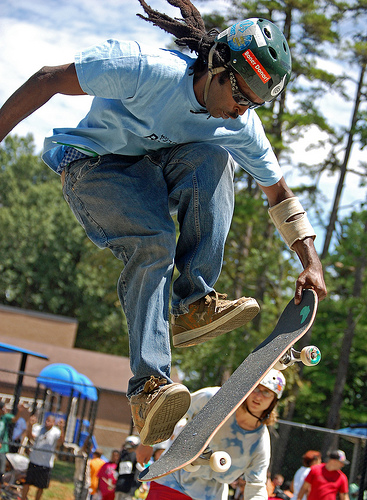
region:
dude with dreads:
[123, 0, 228, 66]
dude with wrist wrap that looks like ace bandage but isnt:
[262, 192, 326, 252]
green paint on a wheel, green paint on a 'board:
[282, 300, 331, 372]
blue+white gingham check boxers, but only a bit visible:
[57, 142, 98, 175]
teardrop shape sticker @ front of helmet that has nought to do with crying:
[266, 70, 293, 103]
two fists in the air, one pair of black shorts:
[18, 411, 71, 498]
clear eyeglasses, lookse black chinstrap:
[238, 381, 278, 429]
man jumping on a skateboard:
[1, 0, 329, 479]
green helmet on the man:
[215, 15, 291, 99]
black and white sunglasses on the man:
[227, 72, 259, 109]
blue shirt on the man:
[42, 41, 283, 186]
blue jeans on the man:
[59, 138, 234, 395]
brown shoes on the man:
[128, 294, 258, 443]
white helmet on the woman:
[254, 370, 283, 397]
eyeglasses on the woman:
[253, 386, 271, 399]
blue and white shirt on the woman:
[153, 388, 272, 499]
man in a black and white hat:
[296, 449, 349, 497]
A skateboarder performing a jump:
[3, 5, 330, 484]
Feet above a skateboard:
[111, 285, 325, 483]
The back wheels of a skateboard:
[181, 444, 232, 478]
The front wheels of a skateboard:
[271, 344, 322, 375]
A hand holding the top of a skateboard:
[286, 266, 333, 312]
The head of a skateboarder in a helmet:
[133, 1, 293, 121]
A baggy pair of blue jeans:
[58, 138, 239, 400]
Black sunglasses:
[228, 72, 266, 116]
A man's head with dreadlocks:
[133, 0, 295, 122]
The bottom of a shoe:
[141, 383, 193, 448]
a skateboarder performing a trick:
[2, 0, 328, 479]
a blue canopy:
[39, 363, 96, 402]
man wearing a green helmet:
[204, 15, 291, 117]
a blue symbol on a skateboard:
[298, 305, 311, 323]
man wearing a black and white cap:
[328, 447, 348, 465]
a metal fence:
[268, 417, 366, 498]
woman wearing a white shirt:
[31, 423, 60, 466]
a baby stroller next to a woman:
[0, 448, 25, 498]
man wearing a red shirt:
[305, 461, 347, 498]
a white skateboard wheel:
[209, 450, 231, 472]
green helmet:
[186, 13, 301, 122]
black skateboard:
[127, 270, 333, 489]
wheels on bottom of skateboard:
[178, 338, 329, 485]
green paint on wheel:
[306, 346, 322, 367]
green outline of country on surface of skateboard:
[290, 297, 316, 329]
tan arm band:
[257, 190, 320, 254]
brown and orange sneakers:
[111, 274, 261, 464]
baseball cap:
[327, 442, 355, 467]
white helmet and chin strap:
[236, 358, 287, 426]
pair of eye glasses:
[248, 382, 279, 400]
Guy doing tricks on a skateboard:
[3, 4, 327, 481]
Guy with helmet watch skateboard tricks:
[142, 368, 286, 498]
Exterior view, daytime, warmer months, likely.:
[0, 2, 362, 499]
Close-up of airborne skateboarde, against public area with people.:
[3, 2, 363, 496]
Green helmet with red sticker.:
[239, 16, 292, 125]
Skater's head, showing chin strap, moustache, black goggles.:
[195, 46, 262, 120]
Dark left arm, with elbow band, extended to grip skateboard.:
[241, 123, 339, 308]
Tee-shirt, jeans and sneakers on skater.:
[77, 54, 272, 456]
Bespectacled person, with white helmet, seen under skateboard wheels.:
[192, 369, 289, 497]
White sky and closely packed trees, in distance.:
[9, 57, 366, 412]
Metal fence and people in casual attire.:
[284, 422, 364, 499]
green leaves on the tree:
[58, 232, 87, 257]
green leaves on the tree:
[345, 416, 362, 434]